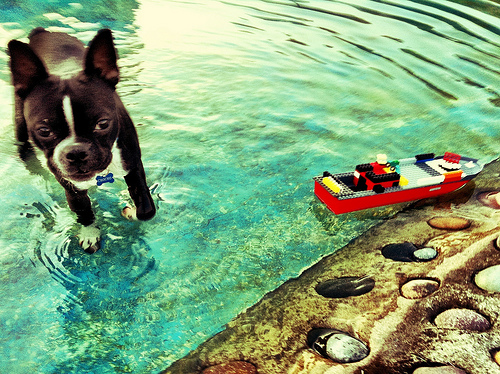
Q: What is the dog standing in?
A: Water.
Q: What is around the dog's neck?
A: A collar.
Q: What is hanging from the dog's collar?
A: Dog license.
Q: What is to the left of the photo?
A: A dog.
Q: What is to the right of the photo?
A: Toy boat.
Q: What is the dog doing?
A: Looking towards the camera.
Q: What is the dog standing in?
A: Water.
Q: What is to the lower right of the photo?
A: Multiple rocks in cement.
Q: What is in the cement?
A: Small stones.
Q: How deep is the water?
A: A few inches.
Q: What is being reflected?
A: The water.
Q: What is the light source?
A: The sun.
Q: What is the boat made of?
A: Legos.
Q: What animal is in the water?
A: Dog.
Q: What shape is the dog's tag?
A: Bone.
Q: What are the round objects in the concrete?
A: Rocks.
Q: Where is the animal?
A: In water.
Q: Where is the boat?
A: In water.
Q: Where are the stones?
A: In concrete.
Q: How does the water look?
A: Clear.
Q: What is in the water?
A: A red toy boat.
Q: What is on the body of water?
A: Ripples are on the water.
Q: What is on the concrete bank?
A: The tip of the boat.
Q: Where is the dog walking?
A: In the shallow water.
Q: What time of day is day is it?
A: Daytime.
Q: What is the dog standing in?
A: A shallow pool of water.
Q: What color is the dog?
A: Black and white.